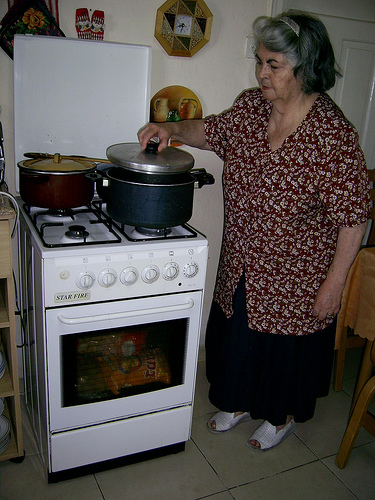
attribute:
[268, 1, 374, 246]
door — white, closed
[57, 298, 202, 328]
handle — white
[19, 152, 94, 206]
pot — red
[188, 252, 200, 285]
knobs — white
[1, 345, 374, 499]
floor — tiled, white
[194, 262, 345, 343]
skirt — long, dark, blue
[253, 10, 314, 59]
hair — gray 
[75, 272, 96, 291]
knob — white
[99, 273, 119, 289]
knob — white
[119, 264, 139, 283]
knob — white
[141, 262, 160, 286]
knob — white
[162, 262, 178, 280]
knob — white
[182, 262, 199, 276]
knob — white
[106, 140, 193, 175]
lid — silver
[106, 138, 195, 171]
lid — pot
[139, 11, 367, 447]
woman — elderly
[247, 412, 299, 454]
shoe — white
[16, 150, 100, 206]
pot — red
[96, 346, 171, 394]
bag — yellow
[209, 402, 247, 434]
right shoe — white